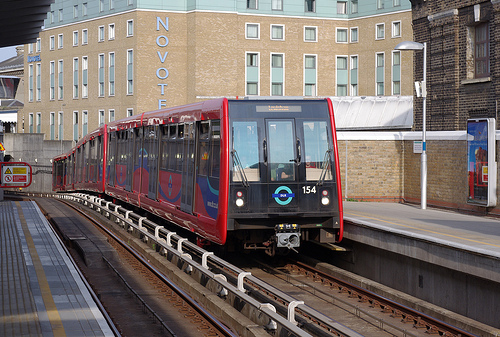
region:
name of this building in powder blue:
[152, 14, 175, 109]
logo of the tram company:
[271, 184, 295, 205]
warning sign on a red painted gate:
[0, 160, 32, 188]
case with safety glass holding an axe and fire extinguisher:
[464, 116, 496, 208]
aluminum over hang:
[0, 0, 54, 48]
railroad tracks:
[122, 257, 482, 335]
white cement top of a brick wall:
[334, 128, 498, 141]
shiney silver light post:
[391, 40, 426, 210]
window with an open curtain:
[241, 50, 257, 68]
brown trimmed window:
[472, 21, 492, 76]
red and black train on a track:
[79, 82, 359, 244]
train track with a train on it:
[14, 147, 418, 315]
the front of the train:
[212, 89, 361, 266]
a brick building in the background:
[26, 15, 456, 121]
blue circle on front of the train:
[269, 178, 296, 211]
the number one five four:
[300, 179, 320, 202]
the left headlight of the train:
[229, 190, 257, 210]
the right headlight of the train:
[313, 185, 334, 211]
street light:
[390, 38, 445, 211]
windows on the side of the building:
[23, 27, 133, 127]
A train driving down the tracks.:
[52, 97, 344, 257]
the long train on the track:
[52, 95, 343, 255]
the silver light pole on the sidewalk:
[394, 40, 427, 208]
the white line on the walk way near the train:
[23, 199, 115, 335]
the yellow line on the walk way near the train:
[13, 198, 66, 335]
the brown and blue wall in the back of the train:
[18, 0, 413, 140]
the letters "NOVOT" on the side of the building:
[157, 15, 169, 94]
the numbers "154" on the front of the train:
[302, 185, 316, 194]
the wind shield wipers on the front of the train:
[231, 128, 333, 184]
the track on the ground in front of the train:
[226, 255, 480, 335]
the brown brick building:
[411, 0, 498, 129]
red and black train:
[192, 85, 374, 263]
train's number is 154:
[293, 173, 330, 218]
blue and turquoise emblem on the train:
[266, 179, 310, 214]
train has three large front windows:
[206, 102, 341, 200]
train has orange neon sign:
[241, 96, 326, 122]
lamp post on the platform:
[395, 30, 443, 213]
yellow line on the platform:
[10, 202, 77, 327]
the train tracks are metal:
[114, 190, 484, 335]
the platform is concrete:
[335, 186, 497, 272]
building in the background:
[4, 19, 458, 136]